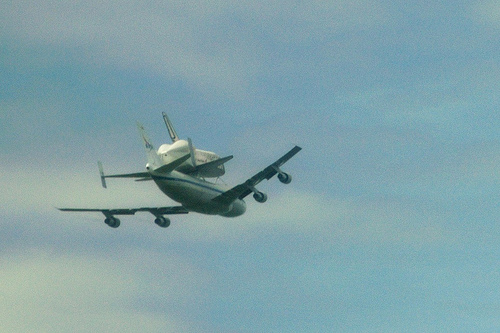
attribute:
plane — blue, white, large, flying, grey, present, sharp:
[48, 123, 311, 242]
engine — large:
[97, 213, 125, 233]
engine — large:
[154, 213, 172, 232]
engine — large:
[250, 186, 268, 205]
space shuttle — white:
[158, 103, 233, 177]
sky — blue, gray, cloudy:
[194, 19, 494, 127]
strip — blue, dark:
[153, 170, 223, 195]